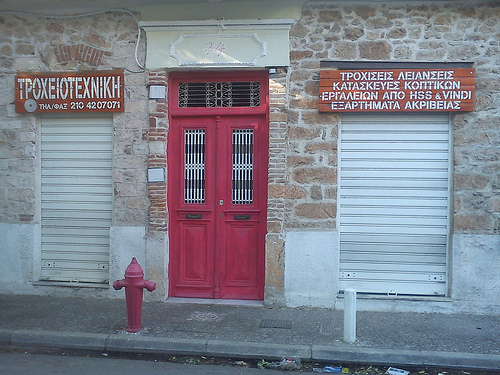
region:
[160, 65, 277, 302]
red door on front of building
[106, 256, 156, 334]
red fire hydrant on street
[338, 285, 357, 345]
white pole on side walk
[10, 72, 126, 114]
brown sign on building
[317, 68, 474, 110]
brown wooden sign on building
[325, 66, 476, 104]
white writing on sign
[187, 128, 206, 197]
metal cage on other side of window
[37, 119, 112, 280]
closed metal shutter on door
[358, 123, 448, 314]
closed metal shutter on door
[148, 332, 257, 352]
concrete curb by street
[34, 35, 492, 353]
a doorway in greece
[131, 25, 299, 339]
the doorway is red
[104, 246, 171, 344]
the fire hydrant on the sidewalk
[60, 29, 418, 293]
stonework is tan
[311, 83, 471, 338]
this doorway has a safety blind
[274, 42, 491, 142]
the greek words are white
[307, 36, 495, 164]
the language is greek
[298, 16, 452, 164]
the sign is orange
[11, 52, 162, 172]
a phone number on sign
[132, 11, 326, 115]
the lintel is white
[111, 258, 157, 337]
hydrant on the sidewalk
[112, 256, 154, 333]
red hydrant on the sidewalk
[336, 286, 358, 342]
pole on the sidewalk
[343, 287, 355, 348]
white pole on the sidewalk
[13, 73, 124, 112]
red and white sign on left side of building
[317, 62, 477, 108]
red and white sign on right side of building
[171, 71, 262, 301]
red door on bulding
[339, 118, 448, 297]
white window covering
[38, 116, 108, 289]
white window covering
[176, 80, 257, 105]
window on top of door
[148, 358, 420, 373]
trash laying in the gutter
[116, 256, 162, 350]
a red fire hydrant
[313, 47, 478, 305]
a white delivery door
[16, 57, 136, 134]
a sign written in Russian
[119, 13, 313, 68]
The street number of the business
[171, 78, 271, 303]
the red door to go into business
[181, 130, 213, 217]
white bars on glass of door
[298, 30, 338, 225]
a red brick wall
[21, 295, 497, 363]
the sidewalk in front of the business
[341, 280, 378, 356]
a white parking marker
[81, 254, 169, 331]
Fire hydrant sitting on the sidewalk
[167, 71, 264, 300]
Red entrence door with black and white windows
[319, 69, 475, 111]
Orange sign in a non english language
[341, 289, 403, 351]
Small white pole on the sidewalk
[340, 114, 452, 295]
Small while gate on the right hand side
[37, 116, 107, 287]
Small white gate on the left hand side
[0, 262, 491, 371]
Sidewalk with a firehydrant and a white pole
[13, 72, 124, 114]
Small orange sign on the left hand side with a disk picture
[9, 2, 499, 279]
Big brick wall covering two gates and a door entrence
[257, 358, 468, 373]
Trash on the side of the road